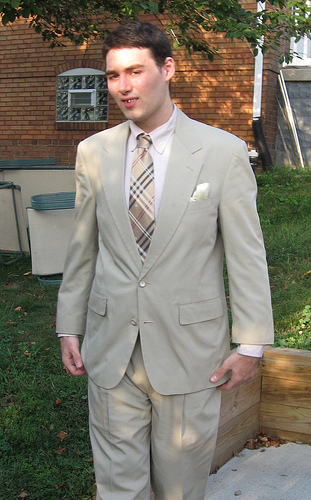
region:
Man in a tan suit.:
[55, 21, 273, 499]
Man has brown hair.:
[102, 19, 171, 97]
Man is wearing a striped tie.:
[129, 133, 154, 265]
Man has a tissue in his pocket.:
[189, 182, 209, 201]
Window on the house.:
[55, 74, 107, 121]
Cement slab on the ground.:
[206, 434, 310, 499]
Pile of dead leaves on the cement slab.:
[245, 431, 287, 450]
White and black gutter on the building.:
[251, 0, 272, 171]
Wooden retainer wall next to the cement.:
[206, 344, 309, 477]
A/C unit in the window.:
[68, 89, 96, 108]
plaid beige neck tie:
[125, 130, 162, 268]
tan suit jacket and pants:
[53, 103, 266, 495]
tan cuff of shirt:
[233, 340, 270, 362]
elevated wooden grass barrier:
[205, 338, 308, 477]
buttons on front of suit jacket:
[119, 273, 154, 334]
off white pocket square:
[181, 174, 219, 213]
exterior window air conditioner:
[60, 81, 102, 111]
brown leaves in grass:
[42, 387, 73, 461]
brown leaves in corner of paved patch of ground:
[242, 426, 289, 456]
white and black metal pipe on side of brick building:
[248, 0, 279, 177]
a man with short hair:
[89, 27, 181, 110]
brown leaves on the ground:
[242, 426, 288, 461]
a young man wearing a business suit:
[78, 48, 193, 316]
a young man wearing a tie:
[114, 137, 160, 235]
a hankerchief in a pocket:
[182, 166, 213, 227]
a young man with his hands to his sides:
[47, 134, 241, 477]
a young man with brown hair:
[82, 19, 168, 93]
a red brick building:
[206, 31, 256, 114]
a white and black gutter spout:
[249, 6, 272, 161]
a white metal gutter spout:
[243, 2, 271, 99]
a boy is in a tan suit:
[45, 16, 279, 498]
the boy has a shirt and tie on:
[125, 133, 161, 264]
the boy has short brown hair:
[97, 17, 174, 73]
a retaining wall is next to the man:
[198, 330, 309, 474]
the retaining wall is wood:
[212, 340, 310, 481]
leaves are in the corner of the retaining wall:
[239, 423, 292, 462]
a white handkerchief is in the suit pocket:
[183, 177, 216, 216]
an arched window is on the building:
[0, 16, 111, 130]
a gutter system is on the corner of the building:
[250, 0, 282, 174]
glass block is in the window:
[57, 74, 108, 121]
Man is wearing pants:
[78, 339, 227, 497]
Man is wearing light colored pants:
[82, 332, 220, 498]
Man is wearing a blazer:
[52, 115, 283, 344]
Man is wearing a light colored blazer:
[51, 100, 275, 347]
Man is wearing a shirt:
[119, 103, 180, 247]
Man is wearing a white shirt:
[123, 100, 176, 224]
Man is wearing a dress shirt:
[124, 103, 181, 224]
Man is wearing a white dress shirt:
[126, 101, 176, 221]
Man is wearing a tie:
[127, 124, 157, 267]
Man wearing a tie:
[127, 125, 157, 262]